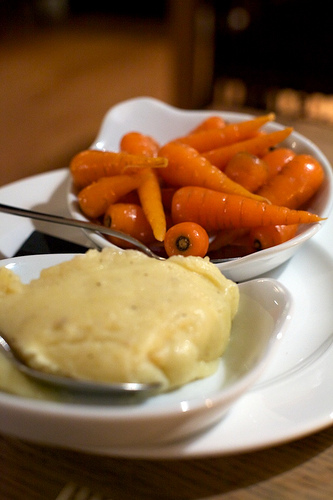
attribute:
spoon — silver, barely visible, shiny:
[0, 325, 168, 402]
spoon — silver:
[0, 200, 259, 266]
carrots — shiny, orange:
[68, 108, 330, 259]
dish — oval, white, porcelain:
[62, 107, 333, 284]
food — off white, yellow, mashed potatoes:
[0, 247, 240, 407]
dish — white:
[0, 249, 294, 450]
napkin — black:
[9, 225, 104, 259]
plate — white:
[0, 164, 333, 461]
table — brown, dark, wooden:
[1, 103, 331, 498]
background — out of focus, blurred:
[3, 2, 327, 187]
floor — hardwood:
[1, 4, 175, 179]